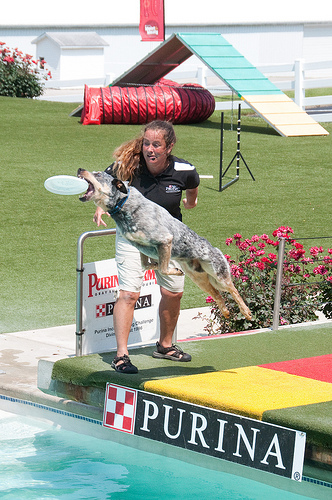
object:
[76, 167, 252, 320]
animal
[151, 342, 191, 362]
sandals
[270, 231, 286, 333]
pole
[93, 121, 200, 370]
lady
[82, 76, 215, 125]
dog tunnel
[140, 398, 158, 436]
letter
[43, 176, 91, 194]
batter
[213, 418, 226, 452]
letter i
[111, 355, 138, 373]
sandal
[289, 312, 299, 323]
leaves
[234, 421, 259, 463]
n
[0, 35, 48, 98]
bush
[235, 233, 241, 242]
flowers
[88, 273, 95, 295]
white letter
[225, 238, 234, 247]
flower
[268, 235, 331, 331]
fence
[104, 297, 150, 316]
purina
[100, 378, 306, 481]
purina sign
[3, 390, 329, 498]
pool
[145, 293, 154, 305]
white letters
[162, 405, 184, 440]
white letters